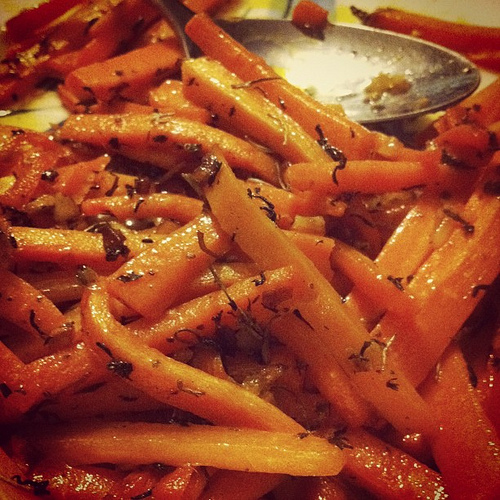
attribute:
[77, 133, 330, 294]
vegetables — cooked, oily, large, cut, covered, orange, rectangular, seasoned, carrots, sliced, skinny, short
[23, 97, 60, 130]
dish — empty, yellow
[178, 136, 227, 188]
herb — green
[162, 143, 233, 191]
herbs — large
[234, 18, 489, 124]
spoon — silver, metal, shiny, used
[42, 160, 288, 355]
carrots — long, yellow